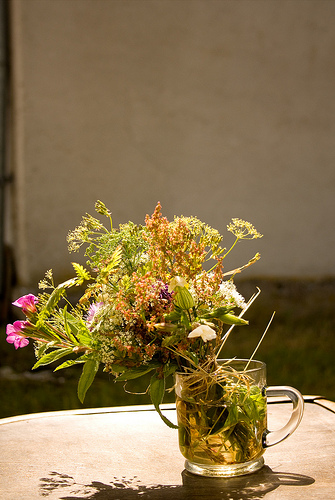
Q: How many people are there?
A: None.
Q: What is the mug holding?
A: Flowers.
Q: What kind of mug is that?
A: Glass.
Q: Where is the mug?
A: On the table.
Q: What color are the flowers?
A: Pink.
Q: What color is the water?
A: Yellow.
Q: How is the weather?
A: Sunny.